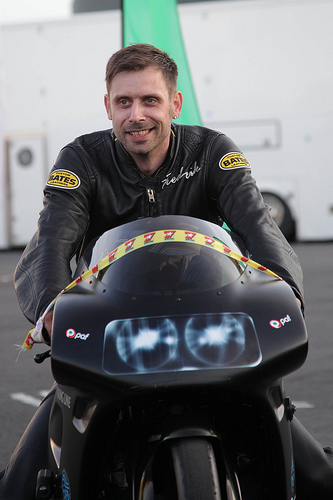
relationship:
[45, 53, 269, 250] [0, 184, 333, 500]
man on bike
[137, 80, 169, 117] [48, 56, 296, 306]
eye on man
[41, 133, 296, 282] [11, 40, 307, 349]
coat on man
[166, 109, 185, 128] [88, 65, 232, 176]
earring on man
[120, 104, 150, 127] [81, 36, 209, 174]
nose of man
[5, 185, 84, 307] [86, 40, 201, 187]
arm of man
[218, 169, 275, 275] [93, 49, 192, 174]
arm of man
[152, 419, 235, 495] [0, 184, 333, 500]
wheel of bike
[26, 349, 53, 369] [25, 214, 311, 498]
brake on motorcycle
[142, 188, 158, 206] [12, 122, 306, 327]
zipper on coat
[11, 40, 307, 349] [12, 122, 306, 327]
man has coat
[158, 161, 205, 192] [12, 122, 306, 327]
writing on coat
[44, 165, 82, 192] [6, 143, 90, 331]
patch on sleeve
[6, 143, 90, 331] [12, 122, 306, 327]
sleeve of coat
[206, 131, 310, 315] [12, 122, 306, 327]
sleeve of coat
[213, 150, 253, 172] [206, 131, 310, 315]
patch on sleeve